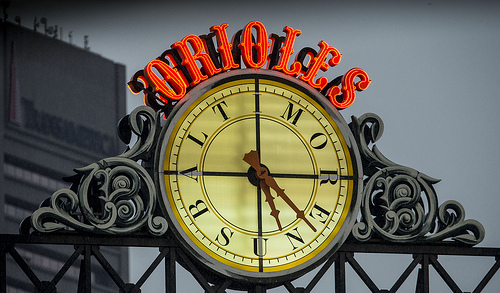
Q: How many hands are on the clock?
A: Two.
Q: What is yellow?
A: Face of clock.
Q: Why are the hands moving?
A: Keeping time.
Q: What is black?
A: The frame.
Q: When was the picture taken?
A: Daytime.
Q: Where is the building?
A: Behind the clock.